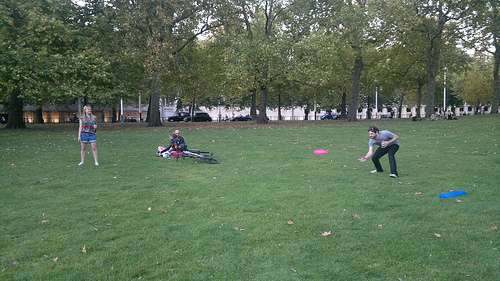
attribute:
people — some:
[62, 96, 412, 186]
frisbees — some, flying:
[304, 142, 475, 222]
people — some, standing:
[54, 103, 410, 187]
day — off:
[8, 3, 492, 280]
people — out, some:
[50, 97, 422, 201]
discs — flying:
[305, 141, 486, 211]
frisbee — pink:
[314, 136, 350, 171]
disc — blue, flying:
[433, 185, 484, 204]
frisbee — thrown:
[276, 141, 375, 168]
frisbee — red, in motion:
[307, 140, 330, 180]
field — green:
[4, 111, 498, 279]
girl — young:
[62, 98, 113, 171]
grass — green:
[5, 115, 498, 279]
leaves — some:
[222, 204, 420, 260]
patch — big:
[210, 209, 344, 254]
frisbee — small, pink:
[308, 143, 344, 169]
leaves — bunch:
[302, 31, 329, 43]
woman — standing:
[74, 101, 104, 176]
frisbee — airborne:
[310, 144, 333, 161]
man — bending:
[364, 122, 404, 175]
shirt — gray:
[366, 129, 395, 152]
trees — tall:
[1, 0, 499, 133]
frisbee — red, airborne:
[312, 141, 329, 157]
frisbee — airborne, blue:
[435, 181, 470, 205]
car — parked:
[165, 106, 210, 125]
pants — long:
[371, 139, 400, 179]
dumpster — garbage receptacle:
[1, 109, 8, 127]